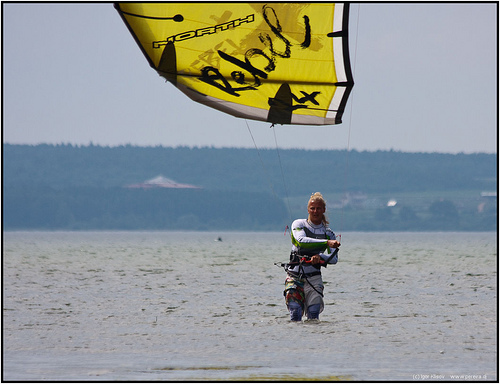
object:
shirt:
[290, 216, 340, 276]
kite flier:
[283, 190, 339, 322]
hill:
[4, 134, 484, 228]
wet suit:
[283, 219, 343, 316]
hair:
[301, 182, 337, 231]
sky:
[0, 9, 483, 156]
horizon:
[1, 127, 483, 165]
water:
[4, 220, 480, 381]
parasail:
[106, 1, 364, 131]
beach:
[0, 228, 499, 382]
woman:
[281, 183, 351, 325]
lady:
[277, 179, 345, 318]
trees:
[6, 139, 489, 232]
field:
[305, 186, 491, 208]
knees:
[282, 300, 326, 321]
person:
[272, 186, 351, 321]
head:
[305, 189, 331, 227]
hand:
[327, 236, 341, 253]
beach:
[14, 373, 407, 383]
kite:
[106, 6, 367, 127]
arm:
[285, 227, 322, 245]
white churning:
[216, 363, 307, 378]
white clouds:
[401, 65, 459, 106]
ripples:
[44, 265, 97, 289]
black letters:
[189, 10, 330, 109]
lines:
[233, 119, 305, 184]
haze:
[8, 8, 110, 84]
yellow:
[118, 6, 373, 130]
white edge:
[328, 3, 359, 124]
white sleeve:
[287, 224, 326, 250]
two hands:
[286, 229, 342, 264]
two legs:
[279, 277, 322, 317]